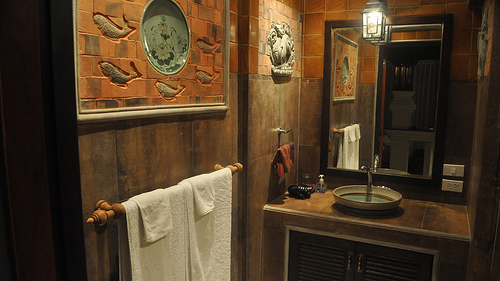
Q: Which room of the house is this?
A: It is a bathroom.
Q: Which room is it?
A: It is a bathroom.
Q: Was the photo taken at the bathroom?
A: Yes, it was taken in the bathroom.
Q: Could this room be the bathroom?
A: Yes, it is the bathroom.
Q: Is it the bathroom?
A: Yes, it is the bathroom.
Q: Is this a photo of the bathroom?
A: Yes, it is showing the bathroom.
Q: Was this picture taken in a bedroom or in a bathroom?
A: It was taken at a bathroom.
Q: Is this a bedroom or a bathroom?
A: It is a bathroom.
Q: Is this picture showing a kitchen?
A: No, the picture is showing a bathroom.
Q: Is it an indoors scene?
A: Yes, it is indoors.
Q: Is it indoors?
A: Yes, it is indoors.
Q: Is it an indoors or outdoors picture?
A: It is indoors.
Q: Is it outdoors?
A: No, it is indoors.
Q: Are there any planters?
A: No, there are no planters.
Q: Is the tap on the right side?
A: Yes, the tap is on the right of the image.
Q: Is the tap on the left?
A: No, the tap is on the right of the image.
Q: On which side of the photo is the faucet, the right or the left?
A: The faucet is on the right of the image.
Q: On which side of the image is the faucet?
A: The faucet is on the right of the image.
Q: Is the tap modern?
A: Yes, the tap is modern.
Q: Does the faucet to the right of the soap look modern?
A: Yes, the faucet is modern.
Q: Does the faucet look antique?
A: No, the faucet is modern.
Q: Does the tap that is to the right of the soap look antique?
A: No, the tap is modern.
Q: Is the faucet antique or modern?
A: The faucet is modern.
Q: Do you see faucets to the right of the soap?
A: Yes, there is a faucet to the right of the soap.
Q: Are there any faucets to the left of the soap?
A: No, the faucet is to the right of the soap.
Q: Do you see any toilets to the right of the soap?
A: No, there is a faucet to the right of the soap.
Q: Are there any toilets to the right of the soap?
A: No, there is a faucet to the right of the soap.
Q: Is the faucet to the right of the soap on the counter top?
A: Yes, the faucet is to the right of the soap.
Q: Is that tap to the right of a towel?
A: No, the tap is to the right of the soap.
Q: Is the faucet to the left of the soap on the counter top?
A: No, the faucet is to the right of the soap.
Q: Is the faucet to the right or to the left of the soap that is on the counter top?
A: The faucet is to the right of the soap.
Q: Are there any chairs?
A: No, there are no chairs.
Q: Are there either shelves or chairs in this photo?
A: No, there are no chairs or shelves.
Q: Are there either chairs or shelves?
A: No, there are no chairs or shelves.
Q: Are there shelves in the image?
A: No, there are no shelves.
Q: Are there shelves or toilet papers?
A: No, there are no shelves or toilet papers.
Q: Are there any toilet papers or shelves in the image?
A: No, there are no shelves or toilet papers.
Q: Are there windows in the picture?
A: Yes, there is a window.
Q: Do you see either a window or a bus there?
A: Yes, there is a window.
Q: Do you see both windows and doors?
A: No, there is a window but no doors.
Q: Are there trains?
A: No, there are no trains.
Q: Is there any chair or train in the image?
A: No, there are no trains or chairs.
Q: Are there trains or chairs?
A: No, there are no trains or chairs.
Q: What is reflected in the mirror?
A: The window is reflected in the mirror.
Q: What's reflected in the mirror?
A: The window is reflected in the mirror.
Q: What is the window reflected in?
A: The window is reflected in the mirror.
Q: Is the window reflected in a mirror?
A: Yes, the window is reflected in a mirror.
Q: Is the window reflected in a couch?
A: No, the window is reflected in a mirror.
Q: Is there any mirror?
A: Yes, there is a mirror.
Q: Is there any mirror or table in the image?
A: Yes, there is a mirror.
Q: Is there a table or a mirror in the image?
A: Yes, there is a mirror.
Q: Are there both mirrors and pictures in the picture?
A: Yes, there are both a mirror and a picture.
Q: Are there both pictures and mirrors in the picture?
A: Yes, there are both a mirror and a picture.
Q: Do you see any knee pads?
A: No, there are no knee pads.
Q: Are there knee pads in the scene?
A: No, there are no knee pads.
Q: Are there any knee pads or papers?
A: No, there are no knee pads or papers.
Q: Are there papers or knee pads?
A: No, there are no knee pads or papers.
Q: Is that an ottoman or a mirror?
A: That is a mirror.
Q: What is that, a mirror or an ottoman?
A: That is a mirror.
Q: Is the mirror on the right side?
A: Yes, the mirror is on the right of the image.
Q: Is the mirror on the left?
A: No, the mirror is on the right of the image.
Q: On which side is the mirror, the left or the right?
A: The mirror is on the right of the image.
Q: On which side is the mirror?
A: The mirror is on the right of the image.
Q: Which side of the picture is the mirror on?
A: The mirror is on the right of the image.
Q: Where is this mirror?
A: The mirror is in the bathroom.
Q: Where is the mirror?
A: The mirror is in the bathroom.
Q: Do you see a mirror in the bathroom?
A: Yes, there is a mirror in the bathroom.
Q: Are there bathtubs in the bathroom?
A: No, there is a mirror in the bathroom.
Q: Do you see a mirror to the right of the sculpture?
A: Yes, there is a mirror to the right of the sculpture.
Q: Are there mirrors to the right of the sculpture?
A: Yes, there is a mirror to the right of the sculpture.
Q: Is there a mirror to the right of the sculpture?
A: Yes, there is a mirror to the right of the sculpture.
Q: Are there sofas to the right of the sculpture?
A: No, there is a mirror to the right of the sculpture.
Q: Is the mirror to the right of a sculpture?
A: Yes, the mirror is to the right of a sculpture.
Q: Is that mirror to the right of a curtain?
A: No, the mirror is to the right of a sculpture.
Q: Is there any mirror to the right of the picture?
A: Yes, there is a mirror to the right of the picture.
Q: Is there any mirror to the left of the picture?
A: No, the mirror is to the right of the picture.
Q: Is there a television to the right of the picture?
A: No, there is a mirror to the right of the picture.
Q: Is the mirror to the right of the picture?
A: Yes, the mirror is to the right of the picture.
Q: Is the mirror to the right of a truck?
A: No, the mirror is to the right of the picture.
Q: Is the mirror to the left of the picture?
A: No, the mirror is to the right of the picture.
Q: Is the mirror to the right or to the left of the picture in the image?
A: The mirror is to the right of the picture.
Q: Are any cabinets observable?
A: Yes, there is a cabinet.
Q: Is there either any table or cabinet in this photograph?
A: Yes, there is a cabinet.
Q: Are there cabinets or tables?
A: Yes, there is a cabinet.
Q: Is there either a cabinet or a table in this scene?
A: Yes, there is a cabinet.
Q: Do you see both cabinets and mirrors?
A: Yes, there are both a cabinet and a mirror.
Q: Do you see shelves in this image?
A: No, there are no shelves.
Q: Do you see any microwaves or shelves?
A: No, there are no shelves or microwaves.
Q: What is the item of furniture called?
A: The piece of furniture is a cabinet.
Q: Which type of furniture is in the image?
A: The furniture is a cabinet.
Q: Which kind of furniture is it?
A: The piece of furniture is a cabinet.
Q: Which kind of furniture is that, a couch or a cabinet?
A: That is a cabinet.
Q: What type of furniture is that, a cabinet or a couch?
A: That is a cabinet.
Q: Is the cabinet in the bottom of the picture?
A: Yes, the cabinet is in the bottom of the image.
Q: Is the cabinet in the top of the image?
A: No, the cabinet is in the bottom of the image.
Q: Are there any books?
A: No, there are no books.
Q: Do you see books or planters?
A: No, there are no books or planters.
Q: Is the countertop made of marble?
A: Yes, the countertop is made of marble.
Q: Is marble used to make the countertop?
A: Yes, the countertop is made of marble.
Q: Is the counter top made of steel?
A: No, the counter top is made of marble.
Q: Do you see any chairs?
A: No, there are no chairs.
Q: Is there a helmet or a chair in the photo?
A: No, there are no chairs or helmets.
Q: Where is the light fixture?
A: The light fixture is in the bathroom.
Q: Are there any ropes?
A: No, there are no ropes.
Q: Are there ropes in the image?
A: No, there are no ropes.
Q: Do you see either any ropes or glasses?
A: No, there are no ropes or glasses.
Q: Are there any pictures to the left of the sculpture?
A: Yes, there is a picture to the left of the sculpture.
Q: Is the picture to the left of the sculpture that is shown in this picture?
A: Yes, the picture is to the left of the sculpture.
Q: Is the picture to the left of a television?
A: No, the picture is to the left of the sculpture.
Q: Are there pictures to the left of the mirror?
A: Yes, there is a picture to the left of the mirror.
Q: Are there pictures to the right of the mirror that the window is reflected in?
A: No, the picture is to the left of the mirror.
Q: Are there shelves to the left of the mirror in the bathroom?
A: No, there is a picture to the left of the mirror.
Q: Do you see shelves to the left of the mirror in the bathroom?
A: No, there is a picture to the left of the mirror.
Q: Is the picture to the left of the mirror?
A: Yes, the picture is to the left of the mirror.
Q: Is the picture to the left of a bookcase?
A: No, the picture is to the left of the mirror.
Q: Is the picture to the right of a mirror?
A: No, the picture is to the left of a mirror.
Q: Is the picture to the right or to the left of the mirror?
A: The picture is to the left of the mirror.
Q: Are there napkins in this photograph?
A: No, there are no napkins.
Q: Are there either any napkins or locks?
A: No, there are no napkins or locks.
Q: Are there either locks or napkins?
A: No, there are no napkins or locks.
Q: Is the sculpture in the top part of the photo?
A: Yes, the sculpture is in the top of the image.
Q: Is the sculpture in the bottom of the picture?
A: No, the sculpture is in the top of the image.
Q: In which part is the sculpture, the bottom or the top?
A: The sculpture is in the top of the image.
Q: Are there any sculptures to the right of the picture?
A: Yes, there is a sculpture to the right of the picture.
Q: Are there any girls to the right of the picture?
A: No, there is a sculpture to the right of the picture.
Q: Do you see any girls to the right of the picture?
A: No, there is a sculpture to the right of the picture.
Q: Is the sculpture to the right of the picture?
A: Yes, the sculpture is to the right of the picture.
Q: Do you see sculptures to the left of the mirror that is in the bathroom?
A: Yes, there is a sculpture to the left of the mirror.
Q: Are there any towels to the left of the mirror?
A: No, there is a sculpture to the left of the mirror.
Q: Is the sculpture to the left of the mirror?
A: Yes, the sculpture is to the left of the mirror.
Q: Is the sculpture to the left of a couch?
A: No, the sculpture is to the left of the mirror.